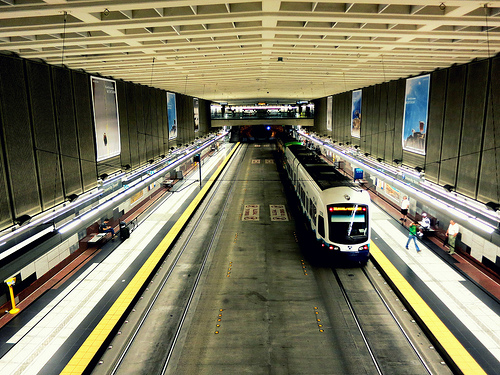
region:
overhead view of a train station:
[10, 5, 491, 366]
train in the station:
[276, 120, 376, 261]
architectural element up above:
[0, 2, 486, 97]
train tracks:
[92, 110, 267, 370]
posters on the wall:
[310, 70, 426, 160]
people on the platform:
[391, 206, 426, 251]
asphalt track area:
[181, 127, 343, 363]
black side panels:
[3, 60, 210, 217]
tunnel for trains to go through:
[214, 118, 289, 144]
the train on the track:
[267, 114, 379, 270]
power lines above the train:
[82, 129, 497, 200]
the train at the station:
[272, 130, 367, 258]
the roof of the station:
[2, 0, 498, 110]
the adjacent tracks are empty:
[106, 143, 252, 372]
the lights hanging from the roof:
[12, 136, 230, 285]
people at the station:
[397, 194, 470, 258]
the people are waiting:
[389, 199, 466, 264]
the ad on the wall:
[383, 75, 449, 172]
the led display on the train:
[325, 198, 363, 215]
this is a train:
[251, 98, 385, 277]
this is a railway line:
[25, 225, 101, 305]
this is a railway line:
[60, 170, 157, 255]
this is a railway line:
[340, 275, 455, 340]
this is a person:
[390, 200, 425, 255]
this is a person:
[430, 210, 460, 260]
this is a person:
[408, 203, 439, 239]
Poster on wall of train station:
[399, 74, 432, 158]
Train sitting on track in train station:
[276, 133, 372, 270]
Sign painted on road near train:
[241, 201, 288, 221]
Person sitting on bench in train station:
[96, 218, 114, 240]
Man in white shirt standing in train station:
[446, 214, 461, 248]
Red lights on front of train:
[328, 245, 370, 251]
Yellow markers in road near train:
[210, 307, 225, 336]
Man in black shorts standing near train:
[399, 193, 410, 221]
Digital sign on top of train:
[331, 204, 361, 211]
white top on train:
[255, 124, 375, 243]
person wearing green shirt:
[405, 219, 422, 244]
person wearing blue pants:
[402, 234, 423, 252]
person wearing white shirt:
[442, 221, 458, 236]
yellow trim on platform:
[381, 257, 479, 369]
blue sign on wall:
[383, 63, 440, 181]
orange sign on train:
[332, 202, 367, 222]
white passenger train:
[279, 131, 374, 268]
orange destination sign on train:
[328, 205, 370, 220]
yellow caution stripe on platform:
[381, 260, 413, 315]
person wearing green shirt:
[405, 219, 420, 254]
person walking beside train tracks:
[405, 220, 420, 252]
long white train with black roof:
[270, 127, 373, 270]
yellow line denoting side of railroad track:
[55, 137, 241, 372]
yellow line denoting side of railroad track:
[365, 231, 488, 373]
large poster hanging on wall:
[400, 73, 432, 159]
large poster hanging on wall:
[348, 84, 363, 140]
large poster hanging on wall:
[162, 87, 177, 137]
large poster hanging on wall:
[85, 70, 120, 160]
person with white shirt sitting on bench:
[413, 209, 435, 238]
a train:
[313, 180, 375, 262]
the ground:
[281, 311, 319, 354]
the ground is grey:
[278, 280, 318, 340]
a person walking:
[404, 219, 424, 251]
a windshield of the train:
[333, 208, 362, 234]